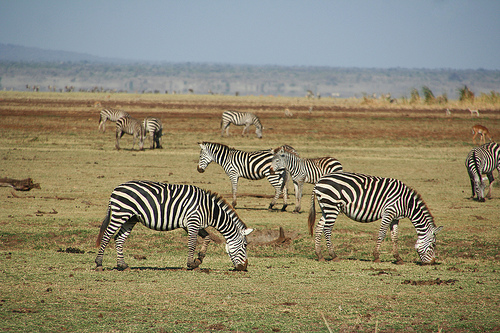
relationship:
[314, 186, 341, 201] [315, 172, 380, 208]
stripe of design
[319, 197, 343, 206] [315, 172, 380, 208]
stripe of design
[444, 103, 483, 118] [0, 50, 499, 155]
animals in background